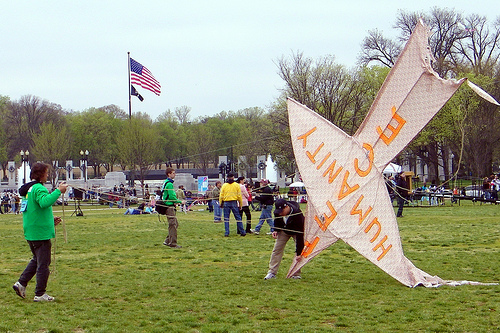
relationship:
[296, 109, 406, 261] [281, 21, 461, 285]
lettering on kite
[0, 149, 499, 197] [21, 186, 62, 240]
background in jacket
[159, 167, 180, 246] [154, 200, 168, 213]
person carrying case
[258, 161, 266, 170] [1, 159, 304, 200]
wreath on building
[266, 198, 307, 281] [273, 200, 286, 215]
man wearing hat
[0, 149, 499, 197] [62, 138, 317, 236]
background holding string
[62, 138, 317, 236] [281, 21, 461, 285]
string to kite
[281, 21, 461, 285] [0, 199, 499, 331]
kite on ground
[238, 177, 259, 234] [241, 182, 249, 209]
person in sweater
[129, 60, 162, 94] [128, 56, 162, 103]
flag of blue flag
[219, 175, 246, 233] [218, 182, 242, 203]
person in jacket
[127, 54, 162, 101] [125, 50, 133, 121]
flags on pole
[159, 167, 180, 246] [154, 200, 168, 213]
person with case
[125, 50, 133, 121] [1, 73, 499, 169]
pole in background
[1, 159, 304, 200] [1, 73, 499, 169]
building in background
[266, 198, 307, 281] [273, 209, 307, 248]
man wearing jacket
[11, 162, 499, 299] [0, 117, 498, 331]
people in park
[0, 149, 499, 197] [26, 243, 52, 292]
background wearing pants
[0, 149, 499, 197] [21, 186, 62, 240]
background wearing jacket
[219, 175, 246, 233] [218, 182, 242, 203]
person wearing jacket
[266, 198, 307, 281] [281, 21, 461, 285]
man flying kite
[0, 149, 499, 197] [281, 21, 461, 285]
background flying kite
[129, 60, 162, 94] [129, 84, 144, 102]
us flag over blue flag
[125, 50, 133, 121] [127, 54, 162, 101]
pole with flags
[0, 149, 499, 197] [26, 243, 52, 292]
background with pants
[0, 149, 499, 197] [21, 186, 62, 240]
background with jacket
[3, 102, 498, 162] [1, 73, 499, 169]
trees in background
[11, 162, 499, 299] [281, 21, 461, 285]
people flying kite